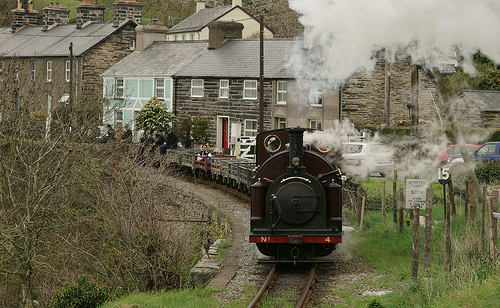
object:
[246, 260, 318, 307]
rail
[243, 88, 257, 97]
window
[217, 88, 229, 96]
window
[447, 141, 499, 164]
cars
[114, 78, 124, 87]
window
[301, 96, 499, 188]
fume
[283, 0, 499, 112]
fume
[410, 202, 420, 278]
post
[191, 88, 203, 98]
window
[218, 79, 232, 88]
window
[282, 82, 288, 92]
window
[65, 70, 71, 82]
window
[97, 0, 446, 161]
building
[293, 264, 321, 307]
metal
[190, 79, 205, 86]
window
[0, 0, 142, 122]
building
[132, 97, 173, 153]
tree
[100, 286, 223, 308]
vegetation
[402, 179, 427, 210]
sign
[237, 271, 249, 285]
rocks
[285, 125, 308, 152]
chimney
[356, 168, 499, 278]
fence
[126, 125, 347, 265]
train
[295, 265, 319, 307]
railway line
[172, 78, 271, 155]
wall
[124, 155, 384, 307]
road